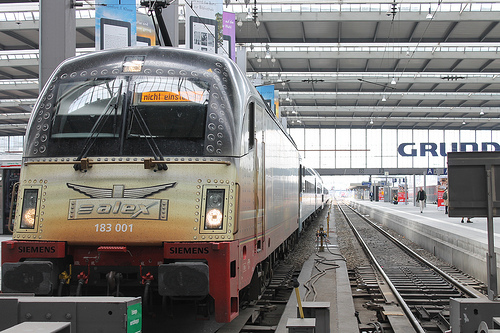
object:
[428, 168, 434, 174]
blue sign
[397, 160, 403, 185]
ground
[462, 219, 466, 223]
feet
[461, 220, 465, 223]
shoes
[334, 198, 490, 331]
rail line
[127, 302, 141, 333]
green sign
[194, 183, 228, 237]
head light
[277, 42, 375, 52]
lightings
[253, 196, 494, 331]
tracks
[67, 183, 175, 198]
eagle logo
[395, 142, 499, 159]
grudd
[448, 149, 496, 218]
sign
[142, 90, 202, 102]
sign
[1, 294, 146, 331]
metal structure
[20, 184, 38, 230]
headlights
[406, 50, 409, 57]
white lights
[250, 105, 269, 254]
door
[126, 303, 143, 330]
stick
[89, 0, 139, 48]
sign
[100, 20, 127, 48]
phone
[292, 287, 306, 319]
pole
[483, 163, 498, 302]
pole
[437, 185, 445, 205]
black bag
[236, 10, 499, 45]
ceiling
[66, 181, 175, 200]
wings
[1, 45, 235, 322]
front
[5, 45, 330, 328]
bus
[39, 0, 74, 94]
beam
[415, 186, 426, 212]
man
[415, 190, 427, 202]
jacket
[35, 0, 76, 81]
pillar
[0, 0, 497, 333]
train station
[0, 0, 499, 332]
station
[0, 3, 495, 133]
roof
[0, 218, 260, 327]
train bottom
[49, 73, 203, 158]
windshield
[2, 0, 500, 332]
photo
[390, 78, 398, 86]
lights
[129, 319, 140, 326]
letters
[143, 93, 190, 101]
letters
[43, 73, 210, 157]
window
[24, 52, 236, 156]
front window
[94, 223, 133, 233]
number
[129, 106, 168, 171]
windshield wiper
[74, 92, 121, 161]
windshield wiper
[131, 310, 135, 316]
lettering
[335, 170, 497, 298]
platform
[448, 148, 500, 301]
metal plate